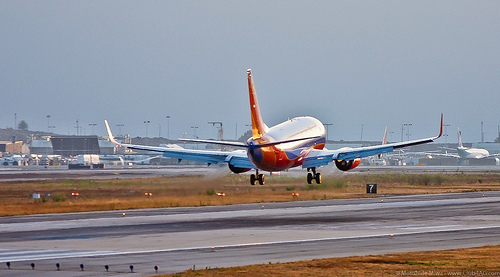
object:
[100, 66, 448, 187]
plane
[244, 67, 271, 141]
tail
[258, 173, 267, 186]
wheel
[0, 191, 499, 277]
runway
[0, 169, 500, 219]
field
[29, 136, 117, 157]
building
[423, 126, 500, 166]
plane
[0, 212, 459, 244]
shadow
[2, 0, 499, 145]
sky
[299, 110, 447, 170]
wing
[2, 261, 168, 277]
line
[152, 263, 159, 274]
light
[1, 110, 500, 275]
airport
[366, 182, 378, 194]
sign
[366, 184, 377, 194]
7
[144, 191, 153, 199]
light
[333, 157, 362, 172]
engine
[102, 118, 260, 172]
wing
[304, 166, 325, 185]
landing gear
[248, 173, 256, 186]
wheel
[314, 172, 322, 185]
wheel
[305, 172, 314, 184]
wheel